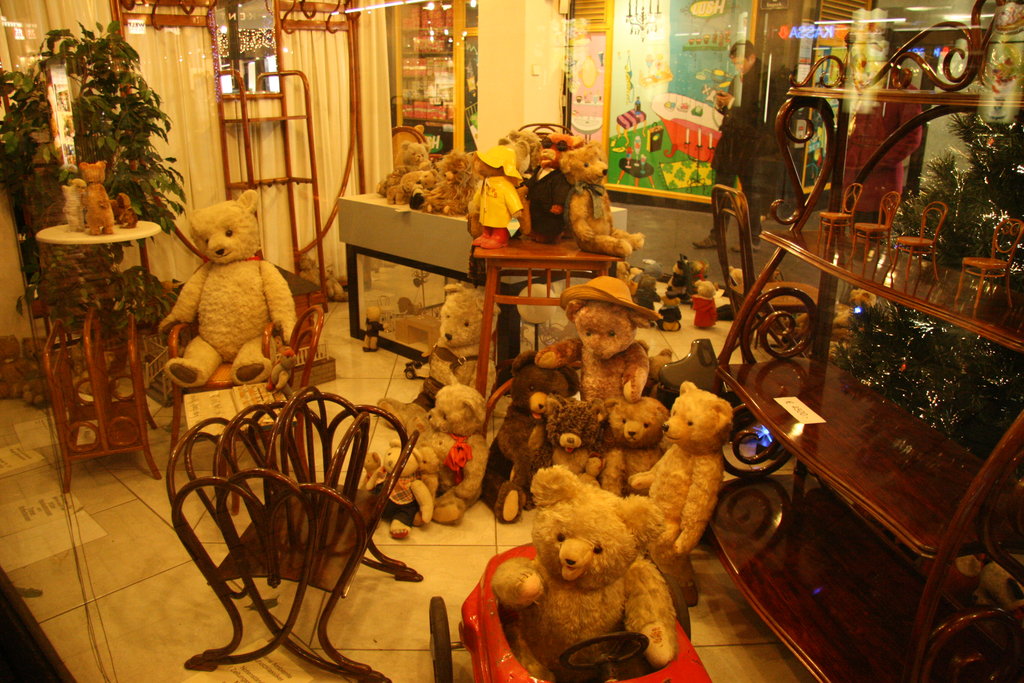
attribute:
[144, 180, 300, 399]
teddy bear — sitting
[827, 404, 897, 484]
wood — brown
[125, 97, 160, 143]
leaves — green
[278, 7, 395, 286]
curtain — white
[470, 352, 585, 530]
teddy bear — dark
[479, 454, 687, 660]
toy — stuffed animal 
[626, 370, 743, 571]
toy — stuffed animal 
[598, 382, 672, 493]
toy — stuffed animal 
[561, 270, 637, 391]
toy — stuffed animal 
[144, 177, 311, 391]
toy — stuffed animal 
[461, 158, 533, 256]
toy — stuffed animal 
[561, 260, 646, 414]
toy — stuffed animal 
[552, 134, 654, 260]
toy — stuffed animal 